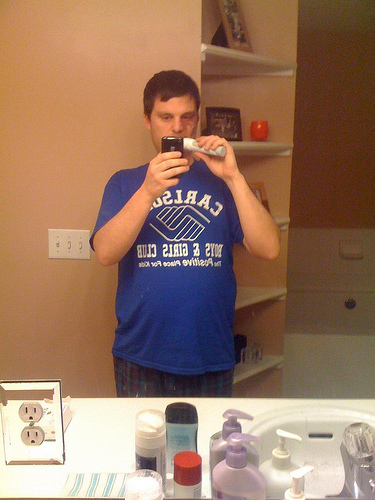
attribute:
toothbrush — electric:
[181, 137, 231, 157]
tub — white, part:
[296, 325, 359, 398]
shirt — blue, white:
[98, 159, 249, 370]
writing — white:
[135, 240, 231, 274]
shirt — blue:
[86, 153, 246, 374]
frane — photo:
[204, 103, 243, 139]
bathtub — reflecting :
[90, 73, 287, 394]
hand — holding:
[143, 152, 227, 221]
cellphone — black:
[157, 126, 240, 181]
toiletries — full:
[117, 395, 320, 499]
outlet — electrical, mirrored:
[0, 379, 65, 463]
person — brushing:
[134, 78, 251, 232]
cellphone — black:
[161, 137, 183, 178]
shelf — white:
[200, 43, 298, 78]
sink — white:
[238, 402, 372, 468]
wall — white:
[0, 1, 192, 397]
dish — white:
[48, 408, 200, 498]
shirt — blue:
[89, 161, 238, 377]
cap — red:
[170, 448, 202, 486]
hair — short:
[142, 68, 203, 123]